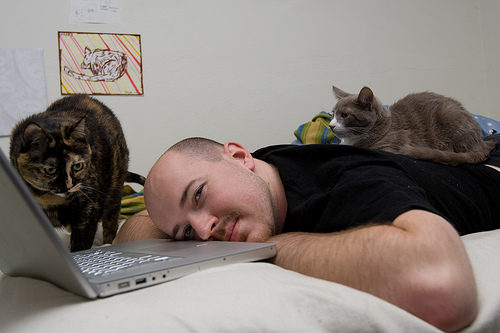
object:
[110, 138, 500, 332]
man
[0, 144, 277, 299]
laptop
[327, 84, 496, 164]
cat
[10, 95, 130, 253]
cat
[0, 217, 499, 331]
comforter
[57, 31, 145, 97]
picture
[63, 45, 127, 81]
cat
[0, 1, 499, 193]
wall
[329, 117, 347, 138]
white face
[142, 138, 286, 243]
head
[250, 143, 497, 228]
back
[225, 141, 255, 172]
ear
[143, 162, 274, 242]
face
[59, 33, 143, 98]
stripes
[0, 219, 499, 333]
bed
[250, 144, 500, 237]
shirt